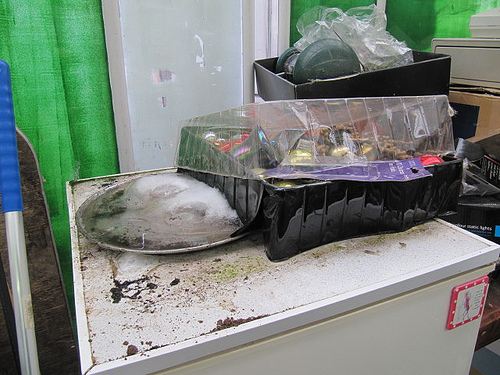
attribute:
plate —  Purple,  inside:
[262, 157, 434, 187]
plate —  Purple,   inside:
[48, 228, 151, 290]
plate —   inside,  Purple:
[123, 65, 160, 82]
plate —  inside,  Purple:
[291, 38, 360, 85]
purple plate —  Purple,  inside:
[258, 160, 432, 180]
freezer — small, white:
[55, 180, 497, 348]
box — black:
[246, 116, 366, 213]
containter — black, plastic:
[189, 97, 478, 246]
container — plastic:
[165, 90, 494, 291]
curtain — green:
[14, 63, 106, 135]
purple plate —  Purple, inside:
[263, 161, 430, 181]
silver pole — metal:
[3, 211, 47, 373]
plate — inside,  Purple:
[82, 173, 247, 244]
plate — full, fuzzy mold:
[70, 170, 262, 256]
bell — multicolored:
[225, 124, 279, 166]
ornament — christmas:
[229, 127, 281, 169]